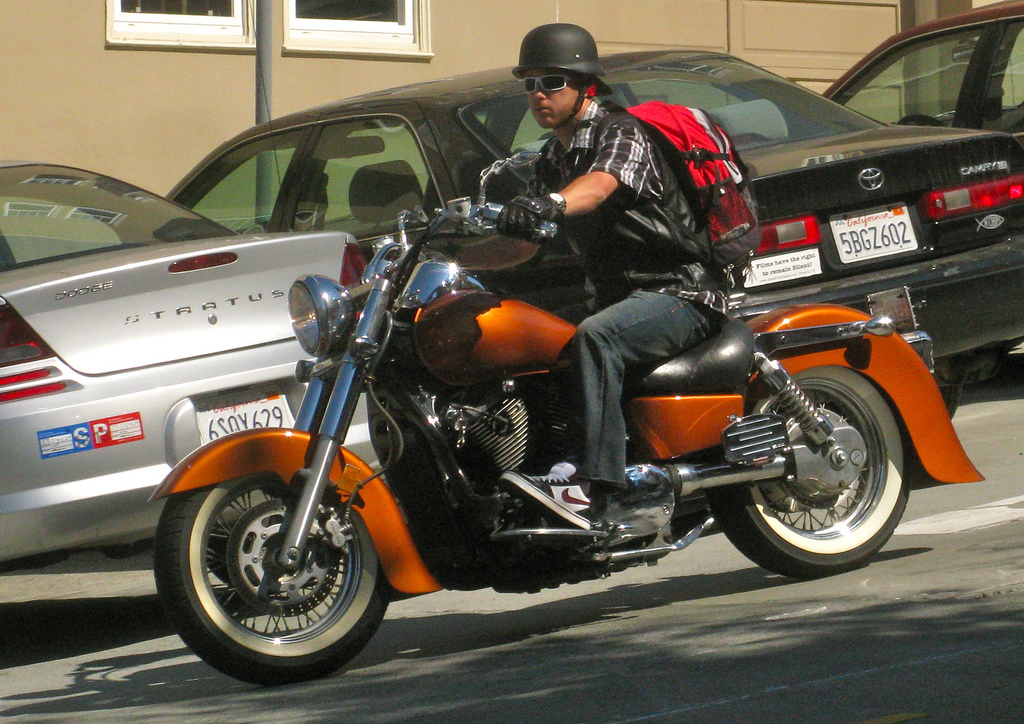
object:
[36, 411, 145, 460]
sticker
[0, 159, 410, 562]
car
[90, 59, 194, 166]
wall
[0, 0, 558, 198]
building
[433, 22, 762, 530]
man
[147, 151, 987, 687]
motorcycle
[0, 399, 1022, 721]
street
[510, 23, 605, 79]
helmet